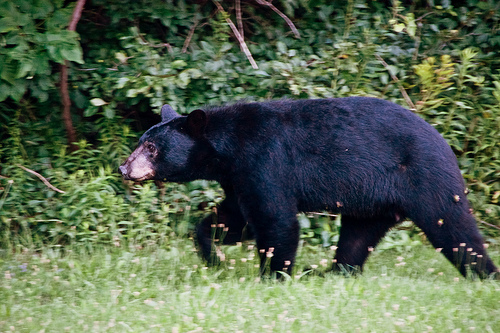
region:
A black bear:
[190, 101, 364, 325]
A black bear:
[228, 80, 338, 255]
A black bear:
[213, 101, 293, 256]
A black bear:
[185, 133, 302, 303]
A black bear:
[237, 134, 323, 294]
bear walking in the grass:
[111, 86, 497, 291]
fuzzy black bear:
[100, 88, 495, 289]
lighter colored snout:
[110, 143, 158, 183]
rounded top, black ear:
[153, 96, 184, 126]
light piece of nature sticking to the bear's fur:
[449, 191, 461, 206]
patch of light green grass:
[0, 236, 497, 331]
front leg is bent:
[179, 187, 248, 274]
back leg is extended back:
[420, 196, 494, 286]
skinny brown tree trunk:
[51, 65, 85, 151]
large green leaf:
[38, 30, 87, 67]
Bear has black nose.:
[104, 158, 132, 218]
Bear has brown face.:
[117, 147, 144, 189]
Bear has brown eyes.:
[129, 135, 171, 172]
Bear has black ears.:
[142, 92, 202, 148]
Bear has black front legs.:
[206, 207, 289, 312]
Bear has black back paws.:
[342, 216, 495, 286]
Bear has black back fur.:
[248, 85, 402, 187]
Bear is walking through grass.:
[182, 227, 374, 331]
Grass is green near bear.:
[143, 244, 210, 322]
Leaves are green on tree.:
[263, 12, 352, 106]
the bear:
[85, 97, 485, 282]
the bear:
[215, 38, 417, 234]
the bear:
[268, 188, 315, 255]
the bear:
[157, 149, 344, 276]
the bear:
[218, 101, 383, 270]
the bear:
[235, 205, 274, 270]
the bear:
[222, 181, 282, 244]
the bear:
[190, 104, 327, 313]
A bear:
[217, 91, 362, 278]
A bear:
[263, 171, 321, 296]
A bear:
[285, 163, 385, 328]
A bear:
[216, 125, 303, 176]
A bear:
[160, 131, 345, 322]